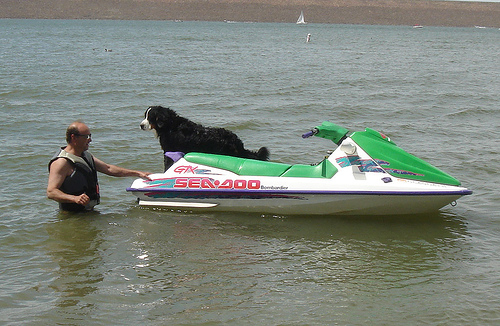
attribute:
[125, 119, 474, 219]
ski — green, purple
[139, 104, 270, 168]
dog — black, hairy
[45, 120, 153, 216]
man — bald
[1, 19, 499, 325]
lake — green, brown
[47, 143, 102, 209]
lifejacket — grey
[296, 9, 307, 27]
boat — behind, white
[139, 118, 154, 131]
nose — white